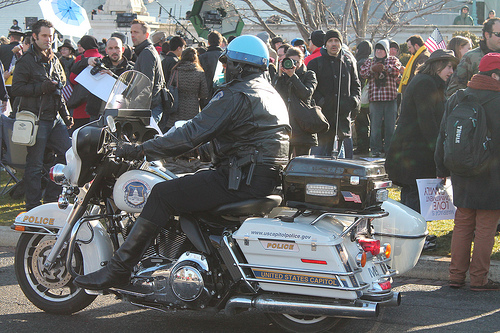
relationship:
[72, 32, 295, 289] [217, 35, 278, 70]
cop wearing blue helmet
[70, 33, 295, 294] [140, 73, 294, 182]
man wearing a coat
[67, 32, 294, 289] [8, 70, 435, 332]
cop is in motorcycle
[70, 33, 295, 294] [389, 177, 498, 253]
man standing on grass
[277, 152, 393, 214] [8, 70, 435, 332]
box on motorcycle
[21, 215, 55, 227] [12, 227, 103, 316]
word on tire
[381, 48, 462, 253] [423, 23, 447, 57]
person holding flag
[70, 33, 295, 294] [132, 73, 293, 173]
man wearing jacket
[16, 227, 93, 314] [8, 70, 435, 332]
tire on motorcycle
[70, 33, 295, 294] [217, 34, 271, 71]
man wearing blue helmet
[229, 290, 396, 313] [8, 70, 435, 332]
exhaust pipe on motorcycle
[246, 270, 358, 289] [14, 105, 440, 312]
united states-capitol on motorcycle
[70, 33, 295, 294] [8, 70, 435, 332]
man written on motorcycle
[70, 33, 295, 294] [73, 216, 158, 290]
man wearing boot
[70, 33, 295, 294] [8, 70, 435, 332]
man on motorcycle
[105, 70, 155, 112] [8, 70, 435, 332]
windscreen on motorcycle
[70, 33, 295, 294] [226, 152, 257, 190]
man wearing pistol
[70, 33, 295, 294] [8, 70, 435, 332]
man riding motorcycle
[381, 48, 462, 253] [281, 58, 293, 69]
person holding camera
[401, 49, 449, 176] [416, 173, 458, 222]
person holding sign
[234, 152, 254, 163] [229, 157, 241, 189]
gun in holster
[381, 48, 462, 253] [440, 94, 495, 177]
person carrying backpack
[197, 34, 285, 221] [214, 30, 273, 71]
man wearing helmet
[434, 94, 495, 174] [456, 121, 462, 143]
backpack with white logo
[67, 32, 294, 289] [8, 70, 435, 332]
cop on motorcycle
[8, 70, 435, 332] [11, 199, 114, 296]
motorcycle has fender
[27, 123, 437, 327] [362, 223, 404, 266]
motorcycle has tail lights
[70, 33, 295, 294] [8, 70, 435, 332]
man has motorcycle